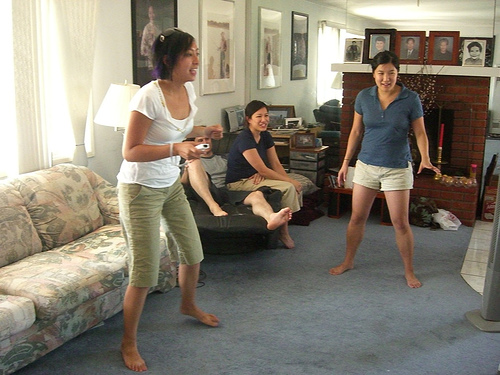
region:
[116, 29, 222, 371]
The excited young woman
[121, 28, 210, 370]
The young woman playing Wii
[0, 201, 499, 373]
A gray carpeted home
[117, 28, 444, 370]
The game excited youth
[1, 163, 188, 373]
The cute patterned couch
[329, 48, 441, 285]
The young woman wearing shorts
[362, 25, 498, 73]
Picture frames up the fireplace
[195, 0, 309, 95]
The hanged wall paintings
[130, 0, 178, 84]
The partially blocked painting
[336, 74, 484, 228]
The central tiled fireplace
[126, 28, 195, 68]
girl has dark hair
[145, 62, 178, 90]
purple streak in hair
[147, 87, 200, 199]
girl has white shirt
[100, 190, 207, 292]
girl has light green pants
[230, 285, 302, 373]
blue carpet on floor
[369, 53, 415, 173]
girl has blue shirt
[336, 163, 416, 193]
girl has white shorts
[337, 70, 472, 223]
red brick fireplace behind woman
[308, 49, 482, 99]
white mantel on fireplace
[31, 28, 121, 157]
white curtain on window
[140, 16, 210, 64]
black and purple hair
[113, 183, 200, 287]
girl has tan pants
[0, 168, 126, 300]
white and green sofa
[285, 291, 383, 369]
carpet is light blue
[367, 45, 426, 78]
woman has dark hair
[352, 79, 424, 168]
woman has blue shirt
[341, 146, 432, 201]
woman has white shorts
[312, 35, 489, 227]
red brick fireplace behind woman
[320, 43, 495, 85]
white shelf on fireplace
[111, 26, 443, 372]
Four people are in a living room.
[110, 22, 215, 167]
A woman has a remote in her hand.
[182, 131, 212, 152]
The color of a remote is white.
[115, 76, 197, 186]
A woman is wearing a white shirt.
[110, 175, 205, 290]
A woman is wearing green pants.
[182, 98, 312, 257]
Two people are sitting down.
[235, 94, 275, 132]
A woman is smiling.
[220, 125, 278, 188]
A woman is wearing a dark shirt.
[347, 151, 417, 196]
A woman is wearing white shorts.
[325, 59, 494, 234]
A fireplace is behind a woman.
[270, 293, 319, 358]
The carpet is blue.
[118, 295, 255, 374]
The woman has no shoes on.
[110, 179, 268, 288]
The woman is wearing tan capri pants.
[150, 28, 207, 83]
The woman has brwon hair.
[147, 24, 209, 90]
The woman has short hair.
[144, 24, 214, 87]
The woman has sunglasses on her head.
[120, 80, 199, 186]
The woman is wearing a white shirt.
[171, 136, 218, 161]
The woman is holding a Wii remote.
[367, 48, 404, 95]
The woman's hair is black.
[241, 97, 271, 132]
The woman's hair is brown.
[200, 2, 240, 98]
a picture in a frame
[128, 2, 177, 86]
a picture in a frame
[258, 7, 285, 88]
a picture in a frame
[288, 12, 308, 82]
a picture in a frame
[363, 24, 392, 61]
a picture in a frame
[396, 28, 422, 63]
a picture in a frame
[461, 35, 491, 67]
a picture in a frame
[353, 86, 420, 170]
dark blue polo shirt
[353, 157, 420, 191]
khaki shorts on girl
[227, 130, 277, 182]
dark blue shirt on girl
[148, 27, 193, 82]
short dark brown hair